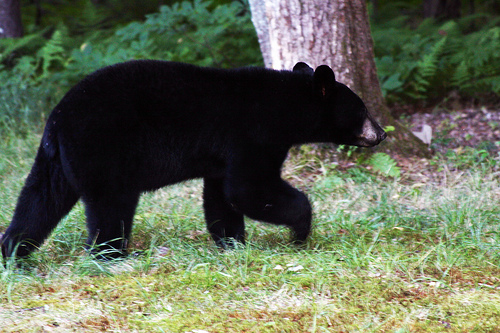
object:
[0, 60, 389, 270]
bear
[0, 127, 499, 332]
grass